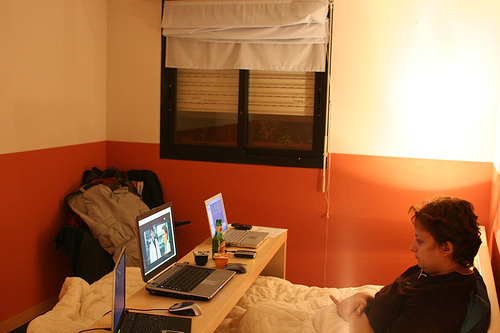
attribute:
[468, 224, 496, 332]
headboard — white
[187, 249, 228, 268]
cups — food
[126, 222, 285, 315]
top — table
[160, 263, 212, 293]
keyboard — black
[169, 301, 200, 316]
mouse — computer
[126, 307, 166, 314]
wire — black, computer, mouse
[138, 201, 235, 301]
laptop — black, silver, middle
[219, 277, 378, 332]
bed — white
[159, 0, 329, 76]
curtains — white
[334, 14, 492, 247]
paint — white, orange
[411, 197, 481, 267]
hair — brown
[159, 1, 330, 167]
window — colored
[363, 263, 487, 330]
shirt — black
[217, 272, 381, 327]
blanket — white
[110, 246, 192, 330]
laptop — one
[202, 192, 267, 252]
laptop — three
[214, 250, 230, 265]
jello — orange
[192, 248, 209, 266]
jello — blue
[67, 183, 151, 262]
pants — beige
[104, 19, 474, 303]
walls — red , white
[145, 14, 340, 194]
window — black 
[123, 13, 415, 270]
wall — white 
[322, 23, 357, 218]
cords — white 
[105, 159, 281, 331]
table — white 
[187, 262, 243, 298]
pad — square 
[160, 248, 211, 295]
keyboard — black 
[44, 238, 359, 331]
bedspread — white 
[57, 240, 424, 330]
bed — white 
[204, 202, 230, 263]
bottle — green 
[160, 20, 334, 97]
curtain — white 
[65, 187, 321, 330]
table — white , narrow 